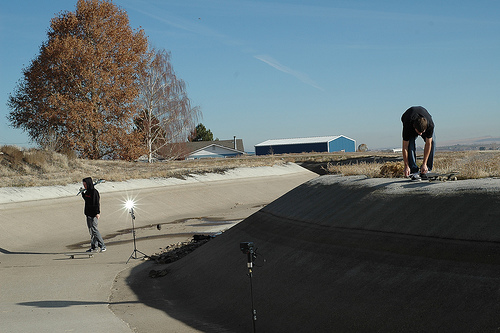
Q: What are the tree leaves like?
A: Brown.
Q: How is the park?
A: The park is cement.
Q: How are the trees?
A: In a group.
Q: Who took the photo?
A: A photographer.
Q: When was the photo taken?
A: Daytime.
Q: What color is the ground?
A: Grey.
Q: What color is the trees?
A: Brown.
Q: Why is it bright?
A: Sunny.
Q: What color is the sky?
A: Blue.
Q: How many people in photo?
A: Two.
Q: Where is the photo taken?
A: On concrete.